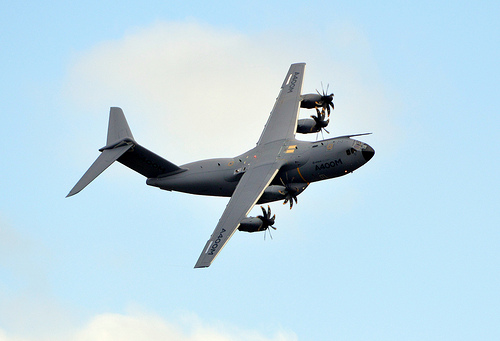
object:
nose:
[359, 141, 376, 162]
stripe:
[296, 167, 307, 183]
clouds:
[106, 207, 175, 276]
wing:
[193, 162, 283, 270]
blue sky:
[0, 0, 500, 341]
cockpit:
[344, 140, 364, 156]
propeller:
[315, 82, 336, 117]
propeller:
[308, 109, 333, 140]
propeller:
[279, 171, 299, 210]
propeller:
[256, 206, 276, 242]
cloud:
[68, 17, 393, 200]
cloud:
[75, 303, 311, 339]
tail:
[65, 106, 180, 197]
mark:
[206, 228, 226, 256]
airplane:
[63, 61, 375, 271]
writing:
[314, 158, 343, 172]